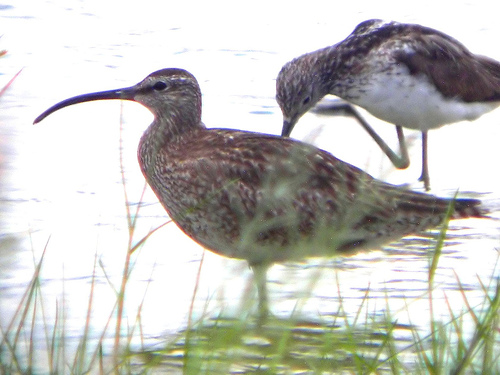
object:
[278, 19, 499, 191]
bird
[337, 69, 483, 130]
belly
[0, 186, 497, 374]
grass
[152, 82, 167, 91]
eye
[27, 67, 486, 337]
birds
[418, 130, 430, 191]
leg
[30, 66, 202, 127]
head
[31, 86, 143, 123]
beak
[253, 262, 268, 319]
leg